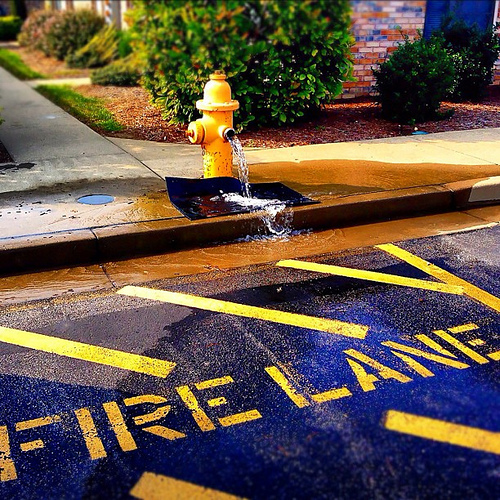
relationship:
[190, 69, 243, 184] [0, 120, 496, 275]
fire hydrant on sidewalk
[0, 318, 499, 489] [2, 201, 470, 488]
words on top of road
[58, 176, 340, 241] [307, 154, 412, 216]
patch on wet sidewalk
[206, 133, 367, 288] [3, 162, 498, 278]
water on curb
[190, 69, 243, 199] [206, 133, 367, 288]
fire hydrant pouring water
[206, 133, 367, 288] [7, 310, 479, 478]
water pouring onto fire lane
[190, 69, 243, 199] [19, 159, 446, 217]
fire hydrant anchored in sidewalk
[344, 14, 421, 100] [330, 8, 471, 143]
bricks on wall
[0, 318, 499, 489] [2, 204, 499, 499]
words on street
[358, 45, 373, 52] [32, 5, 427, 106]
bricks on side of building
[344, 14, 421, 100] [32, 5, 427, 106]
bricks on side of building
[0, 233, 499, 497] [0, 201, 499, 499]
lines on ground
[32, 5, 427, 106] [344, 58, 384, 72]
building made of bricks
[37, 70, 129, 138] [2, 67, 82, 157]
grass beside pavement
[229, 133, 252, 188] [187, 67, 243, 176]
water out of hydrant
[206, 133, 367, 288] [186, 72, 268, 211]
water pouring out hydrant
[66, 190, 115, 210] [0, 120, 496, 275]
hole cover on sidewalk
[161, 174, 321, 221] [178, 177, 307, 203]
mat on floor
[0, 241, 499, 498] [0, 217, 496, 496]
lines on road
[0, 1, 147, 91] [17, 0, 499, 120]
plants growing beside building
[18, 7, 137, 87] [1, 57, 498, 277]
bushes on sidewalk